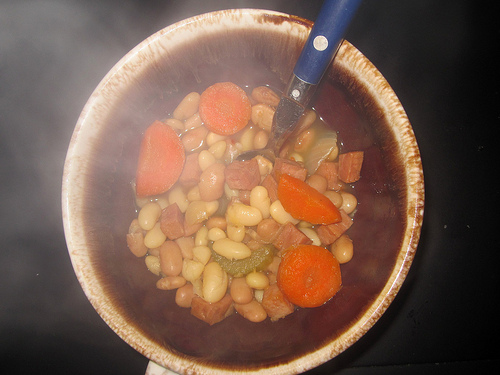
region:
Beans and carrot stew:
[138, 111, 338, 308]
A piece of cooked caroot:
[287, 248, 338, 308]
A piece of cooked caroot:
[278, 174, 345, 225]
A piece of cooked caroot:
[126, 141, 193, 180]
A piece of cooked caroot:
[340, 154, 364, 183]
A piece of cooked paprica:
[211, 244, 276, 276]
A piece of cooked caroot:
[230, 160, 261, 192]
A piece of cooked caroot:
[159, 205, 181, 233]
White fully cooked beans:
[150, 238, 207, 295]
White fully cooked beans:
[217, 209, 259, 254]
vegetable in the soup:
[232, 211, 272, 229]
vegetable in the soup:
[162, 283, 181, 306]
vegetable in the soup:
[280, 240, 340, 300]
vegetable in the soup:
[272, 181, 331, 231]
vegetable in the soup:
[216, 224, 236, 245]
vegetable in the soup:
[197, 173, 234, 205]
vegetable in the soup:
[144, 130, 186, 194]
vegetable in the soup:
[226, 202, 253, 229]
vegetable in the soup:
[155, 242, 182, 287]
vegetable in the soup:
[333, 150, 363, 185]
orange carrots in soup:
[127, 75, 336, 327]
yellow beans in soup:
[161, 125, 311, 334]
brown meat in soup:
[179, 279, 304, 327]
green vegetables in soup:
[222, 211, 292, 283]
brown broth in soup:
[147, 88, 332, 364]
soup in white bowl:
[120, 18, 417, 355]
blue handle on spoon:
[257, 1, 364, 90]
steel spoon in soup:
[240, 44, 325, 198]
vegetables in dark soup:
[77, 75, 354, 327]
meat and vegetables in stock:
[149, 84, 350, 344]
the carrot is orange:
[284, 176, 349, 241]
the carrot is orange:
[275, 263, 356, 324]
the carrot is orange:
[134, 130, 187, 217]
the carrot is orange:
[277, 221, 353, 312]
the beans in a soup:
[135, 121, 325, 303]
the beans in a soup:
[234, 156, 354, 301]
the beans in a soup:
[162, 211, 291, 353]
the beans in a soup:
[205, 234, 351, 356]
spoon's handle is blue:
[297, 11, 350, 96]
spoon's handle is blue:
[276, 5, 360, 115]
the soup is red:
[50, 32, 443, 372]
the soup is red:
[105, 131, 360, 367]